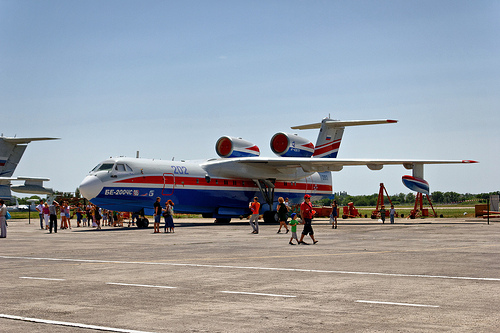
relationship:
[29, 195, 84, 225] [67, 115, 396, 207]
people next to plane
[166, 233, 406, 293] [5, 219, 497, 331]
lines on ground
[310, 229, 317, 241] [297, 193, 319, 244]
leg of adult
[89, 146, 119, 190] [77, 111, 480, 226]
window of plane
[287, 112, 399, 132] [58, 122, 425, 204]
top of plane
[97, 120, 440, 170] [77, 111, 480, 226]
top of plane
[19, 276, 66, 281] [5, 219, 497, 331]
marking strip on ground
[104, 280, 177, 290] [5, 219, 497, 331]
marking strip on ground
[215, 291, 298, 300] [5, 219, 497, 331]
lines on ground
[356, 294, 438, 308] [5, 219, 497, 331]
marking strip on ground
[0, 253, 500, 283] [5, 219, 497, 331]
line on ground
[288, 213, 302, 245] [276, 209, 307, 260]
child in a dress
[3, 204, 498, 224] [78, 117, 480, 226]
fields behind aircraft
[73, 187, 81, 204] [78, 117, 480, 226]
tree behind aircraft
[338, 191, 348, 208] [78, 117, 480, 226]
tree behind aircraft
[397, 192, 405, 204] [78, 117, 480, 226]
tree behind aircraft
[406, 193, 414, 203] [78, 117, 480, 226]
tree behind aircraft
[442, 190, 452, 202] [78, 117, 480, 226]
tree behind aircraft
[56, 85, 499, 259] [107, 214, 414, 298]
plane on ground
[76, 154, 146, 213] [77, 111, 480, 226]
front of plane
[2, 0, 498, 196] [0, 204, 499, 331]
blue sky above land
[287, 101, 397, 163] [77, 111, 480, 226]
tail of plane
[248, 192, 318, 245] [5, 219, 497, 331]
people on ground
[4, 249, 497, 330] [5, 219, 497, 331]
line on ground